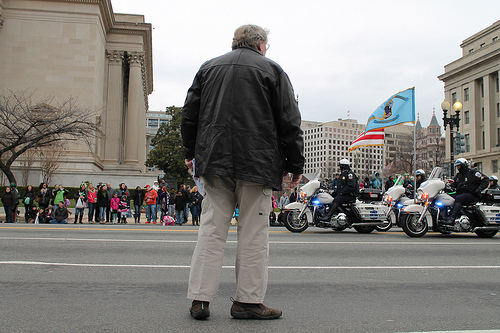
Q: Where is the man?
A: On the side of the road.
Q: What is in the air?
A: Flags.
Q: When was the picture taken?
A: Daytime.